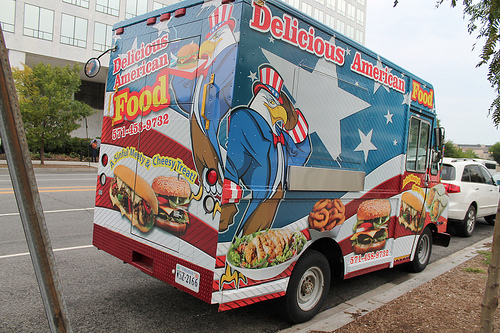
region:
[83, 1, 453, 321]
Truck prepares and serves food on the road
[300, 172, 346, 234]
crispy fried onion rings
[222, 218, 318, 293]
green salads with sliced grilled chicken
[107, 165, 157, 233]
a sub sandwich dressed with cheese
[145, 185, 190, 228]
burger on a sesame roll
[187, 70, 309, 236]
American Bald Eagle dress like Uncle Sam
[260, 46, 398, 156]
white stars on blue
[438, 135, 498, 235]
white SUV parked in road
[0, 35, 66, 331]
pole for a street sign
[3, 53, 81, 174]
young tree planted across the road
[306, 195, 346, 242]
A paper container overflowing with onion rings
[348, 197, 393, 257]
A double cheeseburger on a sesame seed bun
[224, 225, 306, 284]
A white bowl filled with salad and sliced chicken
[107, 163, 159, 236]
A beef and cheese submarine sandwich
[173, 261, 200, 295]
A Virginia license plate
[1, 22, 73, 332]
A partially rusted street sign pole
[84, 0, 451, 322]
An American cuisine food truck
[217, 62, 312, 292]
A cartoon bald eagle in patriotic clothes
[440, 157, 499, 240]
A white car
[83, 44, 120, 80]
A convex mirror attached to back of truck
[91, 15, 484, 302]
a food truck on the street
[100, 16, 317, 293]
this food truck serves sandwiches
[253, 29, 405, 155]
stars on the food truck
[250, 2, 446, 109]
American cusine is served on this truck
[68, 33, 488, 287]
this food truck is parked in the area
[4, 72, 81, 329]
the pole on the street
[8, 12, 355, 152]
a building in the background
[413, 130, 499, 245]
a white car on the road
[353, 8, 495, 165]
a coudy day above the food truck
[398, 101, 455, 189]
a window on the food truck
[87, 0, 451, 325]
red white and blue food truck serving American food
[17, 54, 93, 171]
green tree in background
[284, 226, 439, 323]
black wheels on food truck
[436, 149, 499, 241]
white SUV parked in front of food truck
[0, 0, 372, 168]
white stone office building with windows across street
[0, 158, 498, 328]
concrete roadway with yellow and white stripes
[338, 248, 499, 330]
dirt ground patch under tree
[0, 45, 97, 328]
rsuty metal pole for traffic sign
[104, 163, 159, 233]
picture of hot dog on truck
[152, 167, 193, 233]
hamburger on food truck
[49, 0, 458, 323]
food truck parked at curb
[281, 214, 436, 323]
two food truck wheels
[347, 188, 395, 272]
hamburger picture on side of food truck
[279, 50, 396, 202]
closed window of food truck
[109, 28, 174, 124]
red and yellow lettered Delicious American Food sign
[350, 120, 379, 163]
one white star on blue background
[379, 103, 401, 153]
two white stars on a blue background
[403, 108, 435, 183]
right side window of food truck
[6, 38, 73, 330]
metal street sign pole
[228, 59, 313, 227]
cartoon eagle wearing red white and blue hat